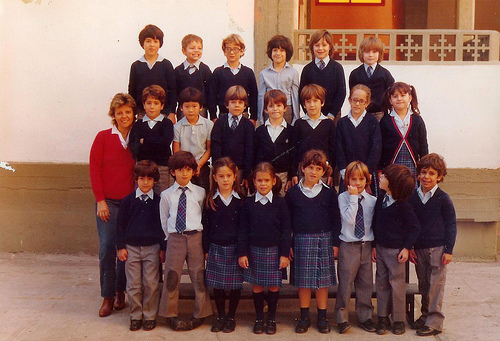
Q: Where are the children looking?
A: At photographer.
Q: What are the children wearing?
A: Uniforms.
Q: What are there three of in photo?
A: Rows of children.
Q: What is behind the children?
A: Walls.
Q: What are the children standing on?
A: Bleachers.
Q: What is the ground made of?
A: Concrete.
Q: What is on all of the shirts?
A: Collars.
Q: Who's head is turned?
A: Second bottom boy.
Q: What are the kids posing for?
A: A picture.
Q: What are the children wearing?
A: School uniforms.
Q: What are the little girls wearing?
A: Shirt and skirt.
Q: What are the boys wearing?
A: Shirt and trousers.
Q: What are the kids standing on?
A: Benches.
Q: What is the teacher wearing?
A: Red sweater.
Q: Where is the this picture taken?
A: School.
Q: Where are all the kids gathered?
A: School playground.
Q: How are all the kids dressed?
A: Neat and tidy.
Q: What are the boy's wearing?
A: Ties.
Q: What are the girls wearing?
A: Sweaters.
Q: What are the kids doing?
A: Posing for photo.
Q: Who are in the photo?
A: People.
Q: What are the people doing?
A: Posing for a picture.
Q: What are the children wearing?
A: Uniform.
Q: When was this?
A: Daytime.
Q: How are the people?
A: Standing.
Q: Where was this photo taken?
A: At a school.